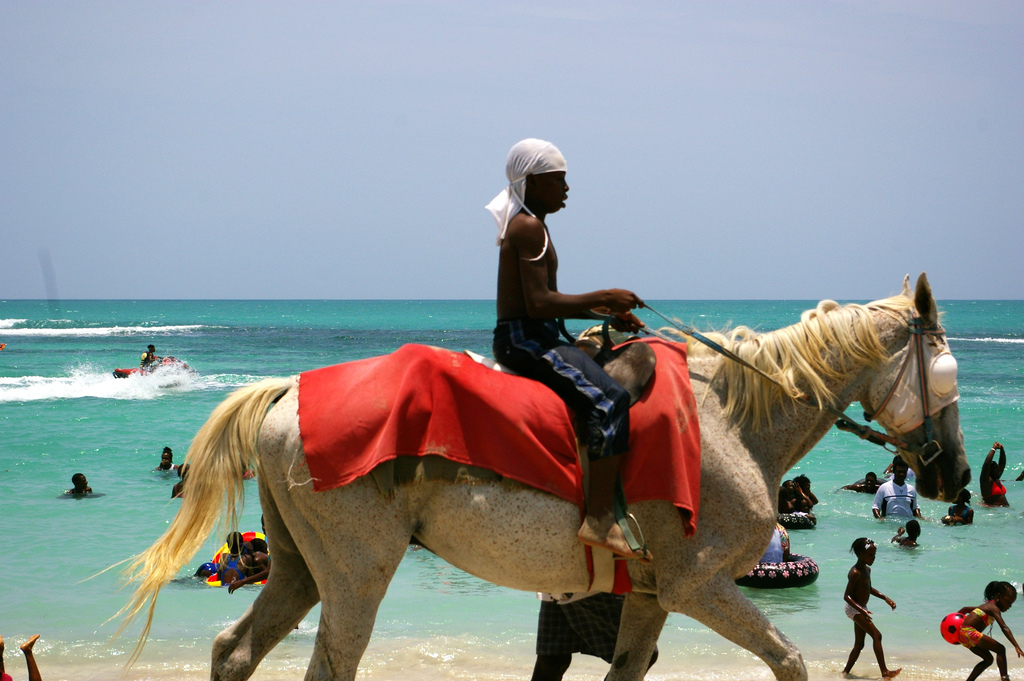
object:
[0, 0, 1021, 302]
sky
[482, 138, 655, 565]
man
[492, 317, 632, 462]
pants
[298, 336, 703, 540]
blanket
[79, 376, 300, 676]
tail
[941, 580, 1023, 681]
person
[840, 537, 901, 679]
person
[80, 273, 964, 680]
horse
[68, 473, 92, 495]
people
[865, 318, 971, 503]
face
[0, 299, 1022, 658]
water